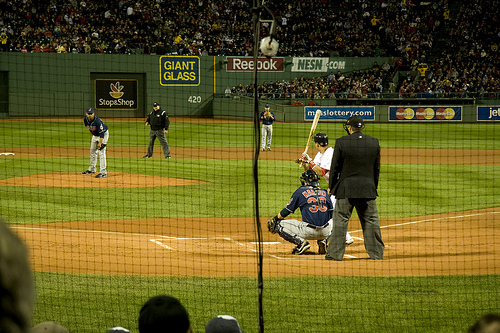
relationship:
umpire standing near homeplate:
[324, 117, 409, 274] [244, 220, 284, 263]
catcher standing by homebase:
[269, 168, 336, 255] [249, 225, 280, 252]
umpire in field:
[131, 97, 175, 164] [1, 111, 497, 331]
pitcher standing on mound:
[69, 90, 131, 202] [15, 170, 200, 190]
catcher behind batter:
[267, 168, 335, 255] [295, 130, 354, 250]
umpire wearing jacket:
[324, 117, 389, 262] [323, 130, 388, 210]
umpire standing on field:
[324, 117, 389, 262] [1, 111, 497, 331]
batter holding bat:
[297, 131, 353, 243] [297, 108, 320, 165]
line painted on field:
[3, 196, 498, 265] [1, 111, 497, 331]